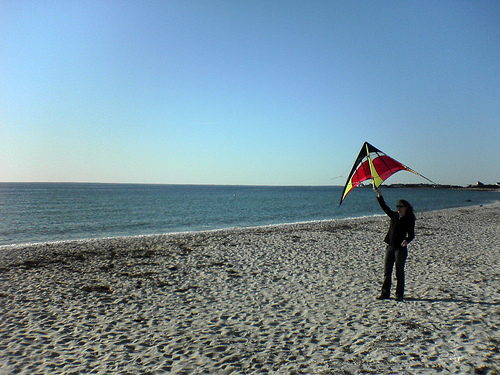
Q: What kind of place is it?
A: It is a beach.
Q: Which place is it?
A: It is a beach.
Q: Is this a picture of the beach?
A: Yes, it is showing the beach.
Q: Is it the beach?
A: Yes, it is the beach.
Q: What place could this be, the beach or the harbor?
A: It is the beach.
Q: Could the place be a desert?
A: No, it is a beach.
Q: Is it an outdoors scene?
A: Yes, it is outdoors.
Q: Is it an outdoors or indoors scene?
A: It is outdoors.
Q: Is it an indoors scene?
A: No, it is outdoors.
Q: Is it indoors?
A: No, it is outdoors.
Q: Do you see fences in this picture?
A: No, there are no fences.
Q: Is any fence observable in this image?
A: No, there are no fences.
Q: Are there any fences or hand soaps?
A: No, there are no fences or hand soaps.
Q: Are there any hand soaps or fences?
A: No, there are no fences or hand soaps.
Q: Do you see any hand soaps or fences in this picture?
A: No, there are no fences or hand soaps.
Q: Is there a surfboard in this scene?
A: No, there are no surfboards.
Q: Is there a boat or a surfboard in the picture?
A: No, there are no surfboards or boats.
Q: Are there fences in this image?
A: No, there are no fences.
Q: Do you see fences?
A: No, there are no fences.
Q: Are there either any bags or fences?
A: No, there are no fences or bags.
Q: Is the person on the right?
A: Yes, the person is on the right of the image.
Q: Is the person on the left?
A: No, the person is on the right of the image.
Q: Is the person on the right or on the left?
A: The person is on the right of the image.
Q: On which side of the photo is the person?
A: The person is on the right of the image.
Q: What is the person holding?
A: The person is holding the kite.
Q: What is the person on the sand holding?
A: The person is holding the kite.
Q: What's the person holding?
A: The person is holding the kite.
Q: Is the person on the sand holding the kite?
A: Yes, the person is holding the kite.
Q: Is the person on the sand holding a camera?
A: No, the person is holding the kite.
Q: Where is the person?
A: The person is on the sand.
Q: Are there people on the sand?
A: Yes, there is a person on the sand.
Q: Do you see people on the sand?
A: Yes, there is a person on the sand.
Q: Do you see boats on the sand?
A: No, there is a person on the sand.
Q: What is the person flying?
A: The person is flying the kite.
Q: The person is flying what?
A: The person is flying the kite.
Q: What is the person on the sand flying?
A: The person is flying the kite.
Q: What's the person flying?
A: The person is flying the kite.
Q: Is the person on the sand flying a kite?
A: Yes, the person is flying a kite.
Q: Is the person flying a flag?
A: No, the person is flying a kite.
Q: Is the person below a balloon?
A: No, the person is below the kite.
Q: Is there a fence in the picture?
A: No, there are no fences.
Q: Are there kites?
A: Yes, there is a kite.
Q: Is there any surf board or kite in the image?
A: Yes, there is a kite.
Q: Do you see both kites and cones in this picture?
A: No, there is a kite but no cones.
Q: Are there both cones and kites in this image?
A: No, there is a kite but no cones.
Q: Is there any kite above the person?
A: Yes, there is a kite above the person.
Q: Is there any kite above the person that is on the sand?
A: Yes, there is a kite above the person.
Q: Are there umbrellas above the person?
A: No, there is a kite above the person.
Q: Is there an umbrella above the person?
A: No, there is a kite above the person.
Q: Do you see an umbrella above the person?
A: No, there is a kite above the person.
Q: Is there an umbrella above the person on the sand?
A: No, there is a kite above the person.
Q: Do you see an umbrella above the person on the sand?
A: No, there is a kite above the person.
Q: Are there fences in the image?
A: No, there are no fences.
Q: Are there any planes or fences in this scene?
A: No, there are no fences or planes.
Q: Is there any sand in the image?
A: Yes, there is sand.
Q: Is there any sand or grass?
A: Yes, there is sand.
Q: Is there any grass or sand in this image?
A: Yes, there is sand.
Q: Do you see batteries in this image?
A: No, there are no batteries.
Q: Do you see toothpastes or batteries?
A: No, there are no batteries or toothpastes.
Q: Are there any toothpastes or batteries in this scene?
A: No, there are no batteries or toothpastes.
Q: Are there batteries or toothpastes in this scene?
A: No, there are no batteries or toothpastes.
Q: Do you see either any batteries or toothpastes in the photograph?
A: No, there are no batteries or toothpastes.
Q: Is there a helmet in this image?
A: No, there are no helmets.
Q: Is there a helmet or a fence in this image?
A: No, there are no helmets or fences.